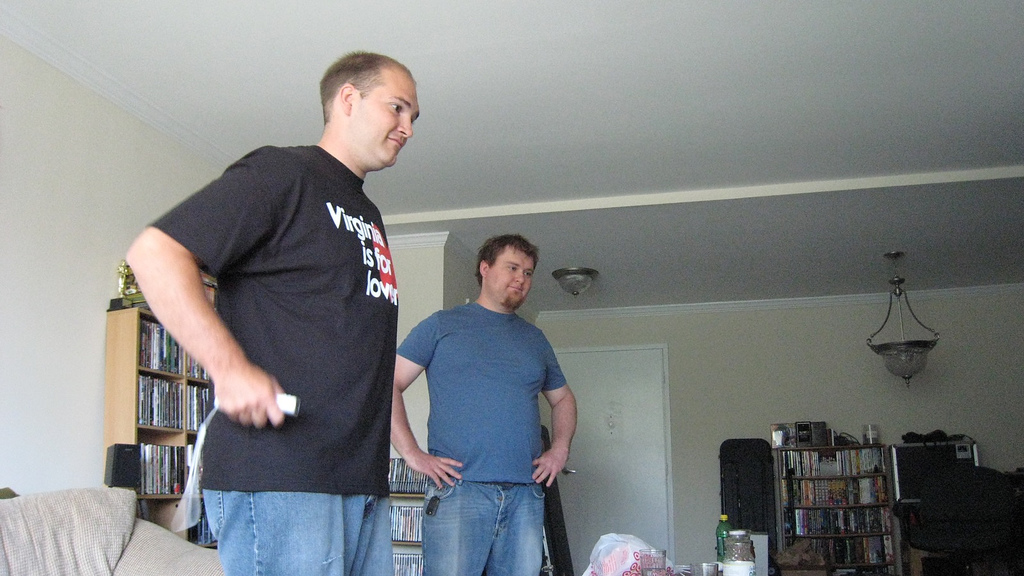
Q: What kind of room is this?
A: It is a living room.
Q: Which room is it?
A: It is a living room.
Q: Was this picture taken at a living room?
A: Yes, it was taken in a living room.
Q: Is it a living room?
A: Yes, it is a living room.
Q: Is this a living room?
A: Yes, it is a living room.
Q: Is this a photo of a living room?
A: Yes, it is showing a living room.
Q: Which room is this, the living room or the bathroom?
A: It is the living room.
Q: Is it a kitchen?
A: No, it is a living room.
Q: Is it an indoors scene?
A: Yes, it is indoors.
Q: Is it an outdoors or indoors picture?
A: It is indoors.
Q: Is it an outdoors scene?
A: No, it is indoors.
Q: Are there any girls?
A: No, there are no girls.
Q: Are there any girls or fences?
A: No, there are no girls or fences.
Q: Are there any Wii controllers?
A: Yes, there is a Wii controller.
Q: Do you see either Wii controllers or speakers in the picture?
A: Yes, there is a Wii controller.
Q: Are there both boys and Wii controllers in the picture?
A: No, there is a Wii controller but no boys.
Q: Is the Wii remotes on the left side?
A: Yes, the Wii remotes is on the left of the image.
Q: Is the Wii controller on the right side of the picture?
A: No, the Wii controller is on the left of the image.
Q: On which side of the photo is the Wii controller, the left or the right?
A: The Wii controller is on the left of the image.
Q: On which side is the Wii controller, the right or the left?
A: The Wii controller is on the left of the image.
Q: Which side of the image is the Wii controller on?
A: The Wii controller is on the left of the image.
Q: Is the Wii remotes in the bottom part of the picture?
A: Yes, the Wii remotes is in the bottom of the image.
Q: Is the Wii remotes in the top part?
A: No, the Wii remotes is in the bottom of the image.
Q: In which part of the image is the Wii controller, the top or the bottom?
A: The Wii controller is in the bottom of the image.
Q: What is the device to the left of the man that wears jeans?
A: The device is a Wii controller.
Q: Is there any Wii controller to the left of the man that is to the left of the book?
A: Yes, there is a Wii controller to the left of the man.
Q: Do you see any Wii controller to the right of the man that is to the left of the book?
A: No, the Wii controller is to the left of the man.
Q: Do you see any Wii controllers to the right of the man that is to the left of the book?
A: No, the Wii controller is to the left of the man.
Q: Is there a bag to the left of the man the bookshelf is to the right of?
A: No, there is a Wii controller to the left of the man.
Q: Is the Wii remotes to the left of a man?
A: Yes, the Wii remotes is to the left of a man.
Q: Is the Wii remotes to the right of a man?
A: No, the Wii remotes is to the left of a man.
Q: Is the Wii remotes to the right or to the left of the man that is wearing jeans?
A: The Wii remotes is to the left of the man.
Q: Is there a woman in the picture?
A: No, there are no women.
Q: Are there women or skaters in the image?
A: No, there are no women or skaters.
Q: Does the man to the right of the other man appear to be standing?
A: Yes, the man is standing.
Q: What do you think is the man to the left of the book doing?
A: The man is standing.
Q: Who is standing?
A: The man is standing.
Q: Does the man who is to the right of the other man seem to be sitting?
A: No, the man is standing.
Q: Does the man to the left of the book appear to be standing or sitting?
A: The man is standing.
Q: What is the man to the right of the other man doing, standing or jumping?
A: The man is standing.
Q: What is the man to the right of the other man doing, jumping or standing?
A: The man is standing.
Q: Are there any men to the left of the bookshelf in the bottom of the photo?
A: Yes, there is a man to the left of the bookshelf.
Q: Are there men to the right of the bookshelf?
A: No, the man is to the left of the bookshelf.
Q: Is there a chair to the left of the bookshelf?
A: No, there is a man to the left of the bookshelf.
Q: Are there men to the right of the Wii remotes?
A: Yes, there is a man to the right of the Wii remotes.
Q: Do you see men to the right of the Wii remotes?
A: Yes, there is a man to the right of the Wii remotes.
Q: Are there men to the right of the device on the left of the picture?
A: Yes, there is a man to the right of the Wii remotes.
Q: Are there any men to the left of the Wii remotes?
A: No, the man is to the right of the Wii remotes.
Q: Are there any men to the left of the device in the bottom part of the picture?
A: No, the man is to the right of the Wii remotes.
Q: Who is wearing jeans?
A: The man is wearing jeans.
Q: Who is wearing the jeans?
A: The man is wearing jeans.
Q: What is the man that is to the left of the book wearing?
A: The man is wearing jeans.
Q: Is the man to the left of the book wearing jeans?
A: Yes, the man is wearing jeans.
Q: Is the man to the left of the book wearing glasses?
A: No, the man is wearing jeans.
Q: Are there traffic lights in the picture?
A: No, there are no traffic lights.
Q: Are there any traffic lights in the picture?
A: No, there are no traffic lights.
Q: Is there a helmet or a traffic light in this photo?
A: No, there are no traffic lights or helmets.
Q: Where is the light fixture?
A: The light fixture is in the living room.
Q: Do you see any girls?
A: No, there are no girls.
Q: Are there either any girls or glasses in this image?
A: No, there are no girls or glasses.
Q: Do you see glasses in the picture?
A: No, there are no glasses.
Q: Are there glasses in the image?
A: No, there are no glasses.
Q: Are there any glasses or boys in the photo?
A: No, there are no glasses or boys.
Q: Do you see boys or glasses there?
A: No, there are no glasses or boys.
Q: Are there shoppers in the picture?
A: No, there are no shoppers.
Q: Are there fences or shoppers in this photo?
A: No, there are no shoppers or fences.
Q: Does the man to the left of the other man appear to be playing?
A: Yes, the man is playing.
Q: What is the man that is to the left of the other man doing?
A: The man is playing.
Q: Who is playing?
A: The man is playing.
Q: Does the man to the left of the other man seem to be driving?
A: No, the man is playing.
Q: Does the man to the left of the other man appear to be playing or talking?
A: The man is playing.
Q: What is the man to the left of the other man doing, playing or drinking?
A: The man is playing.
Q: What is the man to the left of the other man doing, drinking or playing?
A: The man is playing.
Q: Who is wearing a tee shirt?
A: The man is wearing a tee shirt.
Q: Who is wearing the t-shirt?
A: The man is wearing a tee shirt.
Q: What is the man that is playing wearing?
A: The man is wearing a tshirt.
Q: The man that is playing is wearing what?
A: The man is wearing a tshirt.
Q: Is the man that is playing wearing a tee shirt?
A: Yes, the man is wearing a tee shirt.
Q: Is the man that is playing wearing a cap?
A: No, the man is wearing a tee shirt.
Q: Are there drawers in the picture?
A: No, there are no drawers.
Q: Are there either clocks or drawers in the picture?
A: No, there are no drawers or clocks.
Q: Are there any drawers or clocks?
A: No, there are no drawers or clocks.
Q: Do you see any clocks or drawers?
A: No, there are no drawers or clocks.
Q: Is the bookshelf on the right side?
A: Yes, the bookshelf is on the right of the image.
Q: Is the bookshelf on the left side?
A: No, the bookshelf is on the right of the image.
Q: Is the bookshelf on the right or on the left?
A: The bookshelf is on the right of the image.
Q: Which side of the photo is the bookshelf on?
A: The bookshelf is on the right of the image.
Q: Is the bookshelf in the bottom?
A: Yes, the bookshelf is in the bottom of the image.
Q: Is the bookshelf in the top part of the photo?
A: No, the bookshelf is in the bottom of the image.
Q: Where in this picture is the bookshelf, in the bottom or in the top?
A: The bookshelf is in the bottom of the image.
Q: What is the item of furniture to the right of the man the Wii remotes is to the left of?
A: The piece of furniture is a bookshelf.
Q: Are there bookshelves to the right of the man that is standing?
A: Yes, there is a bookshelf to the right of the man.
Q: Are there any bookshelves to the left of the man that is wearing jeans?
A: No, the bookshelf is to the right of the man.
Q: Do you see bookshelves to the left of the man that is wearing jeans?
A: No, the bookshelf is to the right of the man.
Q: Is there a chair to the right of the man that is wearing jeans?
A: No, there is a bookshelf to the right of the man.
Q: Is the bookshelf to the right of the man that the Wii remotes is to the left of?
A: Yes, the bookshelf is to the right of the man.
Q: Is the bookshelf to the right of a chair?
A: No, the bookshelf is to the right of the man.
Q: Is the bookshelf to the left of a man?
A: No, the bookshelf is to the right of a man.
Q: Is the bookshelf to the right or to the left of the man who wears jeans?
A: The bookshelf is to the right of the man.